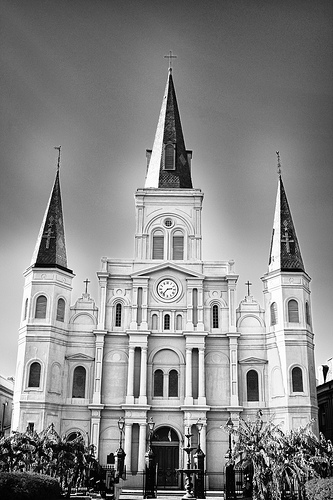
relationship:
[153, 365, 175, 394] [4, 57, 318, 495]
window of building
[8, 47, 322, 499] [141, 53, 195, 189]
building has stepple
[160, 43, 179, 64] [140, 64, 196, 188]
cross on steeple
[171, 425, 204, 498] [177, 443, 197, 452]
statue has shelve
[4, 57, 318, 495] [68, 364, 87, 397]
building has window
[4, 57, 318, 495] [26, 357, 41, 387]
building has window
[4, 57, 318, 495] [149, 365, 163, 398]
building has window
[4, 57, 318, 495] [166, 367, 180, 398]
building has window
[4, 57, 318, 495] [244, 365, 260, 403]
building has window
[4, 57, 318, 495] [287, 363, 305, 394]
building has window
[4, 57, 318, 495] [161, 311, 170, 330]
building has window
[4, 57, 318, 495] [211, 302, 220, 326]
building has window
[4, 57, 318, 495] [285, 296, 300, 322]
building has window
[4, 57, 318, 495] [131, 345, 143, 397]
building has window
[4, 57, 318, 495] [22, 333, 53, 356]
building has wall